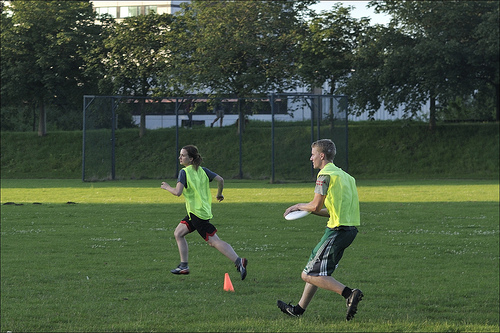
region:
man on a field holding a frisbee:
[273, 134, 366, 323]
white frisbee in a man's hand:
[283, 203, 313, 220]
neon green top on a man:
[310, 165, 368, 229]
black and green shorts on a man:
[303, 224, 358, 278]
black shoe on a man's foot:
[275, 295, 302, 319]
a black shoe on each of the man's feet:
[273, 288, 368, 320]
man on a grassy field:
[271, 135, 366, 323]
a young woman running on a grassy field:
[148, 137, 260, 277]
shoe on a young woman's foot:
[170, 262, 192, 277]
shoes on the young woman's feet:
[168, 255, 253, 277]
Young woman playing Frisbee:
[160, 143, 250, 281]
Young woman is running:
[157, 143, 249, 279]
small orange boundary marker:
[222, 273, 234, 293]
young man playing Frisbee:
[274, 138, 363, 320]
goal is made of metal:
[80, 91, 348, 181]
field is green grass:
[0, 178, 499, 332]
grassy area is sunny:
[0, 184, 498, 206]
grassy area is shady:
[1, 201, 498, 331]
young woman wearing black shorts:
[178, 212, 217, 243]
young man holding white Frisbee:
[283, 208, 311, 222]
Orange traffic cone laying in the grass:
[220, 270, 237, 295]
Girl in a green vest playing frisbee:
[157, 143, 252, 282]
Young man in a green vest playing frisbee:
[275, 134, 360, 331]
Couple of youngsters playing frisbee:
[157, 140, 362, 327]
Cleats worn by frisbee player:
[345, 287, 366, 319]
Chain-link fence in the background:
[80, 90, 352, 180]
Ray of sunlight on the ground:
[0, 184, 498, 202]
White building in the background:
[104, 74, 433, 131]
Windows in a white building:
[113, 90, 287, 115]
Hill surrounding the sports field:
[2, 118, 499, 184]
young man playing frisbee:
[276, 135, 367, 319]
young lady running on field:
[161, 140, 251, 283]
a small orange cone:
[218, 267, 236, 294]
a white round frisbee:
[283, 208, 308, 223]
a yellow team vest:
[316, 161, 362, 231]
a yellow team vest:
[177, 163, 210, 218]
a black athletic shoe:
[272, 295, 301, 317]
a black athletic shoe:
[343, 285, 363, 320]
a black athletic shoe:
[233, 255, 250, 278]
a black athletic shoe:
[166, 263, 191, 278]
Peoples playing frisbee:
[141, 135, 381, 318]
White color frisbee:
[284, 200, 313, 227]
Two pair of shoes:
[169, 250, 371, 320]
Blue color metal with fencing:
[82, 93, 359, 181]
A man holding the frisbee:
[269, 136, 379, 320]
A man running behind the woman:
[156, 130, 393, 318]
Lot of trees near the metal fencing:
[24, 11, 442, 86]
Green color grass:
[33, 169, 155, 261]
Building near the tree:
[102, 6, 343, 111]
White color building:
[138, 75, 350, 127]